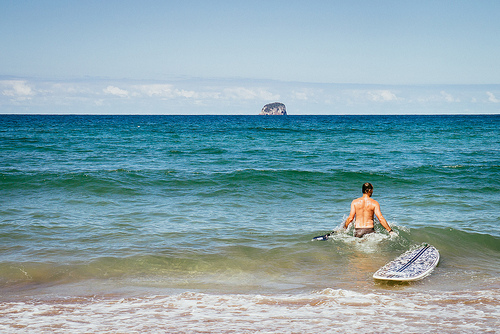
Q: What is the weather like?
A: It is clear.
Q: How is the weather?
A: It is clear.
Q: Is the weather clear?
A: Yes, it is clear.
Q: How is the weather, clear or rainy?
A: It is clear.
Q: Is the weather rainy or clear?
A: It is clear.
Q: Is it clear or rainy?
A: It is clear.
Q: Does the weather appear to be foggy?
A: No, it is clear.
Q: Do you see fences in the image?
A: No, there are no fences.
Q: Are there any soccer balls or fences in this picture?
A: No, there are no fences or soccer balls.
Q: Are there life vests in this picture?
A: No, there are no life vests.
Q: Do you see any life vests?
A: No, there are no life vests.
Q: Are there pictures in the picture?
A: No, there are no pictures.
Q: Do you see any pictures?
A: No, there are no pictures.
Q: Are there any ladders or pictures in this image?
A: No, there are no pictures or ladders.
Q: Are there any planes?
A: No, there are no planes.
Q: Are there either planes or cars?
A: No, there are no planes or cars.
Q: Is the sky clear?
A: Yes, the sky is clear.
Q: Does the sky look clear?
A: Yes, the sky is clear.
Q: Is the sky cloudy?
A: No, the sky is clear.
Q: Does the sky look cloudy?
A: No, the sky is clear.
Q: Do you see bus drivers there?
A: No, there are no bus drivers.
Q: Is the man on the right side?
A: Yes, the man is on the right of the image.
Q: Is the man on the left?
A: No, the man is on the right of the image.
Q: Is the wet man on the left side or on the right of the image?
A: The man is on the right of the image.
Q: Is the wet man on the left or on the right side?
A: The man is on the right of the image.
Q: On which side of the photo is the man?
A: The man is on the right of the image.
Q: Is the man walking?
A: Yes, the man is walking.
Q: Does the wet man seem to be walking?
A: Yes, the man is walking.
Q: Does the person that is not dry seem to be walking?
A: Yes, the man is walking.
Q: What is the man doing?
A: The man is walking.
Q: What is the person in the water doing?
A: The man is walking.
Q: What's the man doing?
A: The man is walking.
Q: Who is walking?
A: The man is walking.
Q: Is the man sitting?
A: No, the man is walking.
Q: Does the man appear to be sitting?
A: No, the man is walking.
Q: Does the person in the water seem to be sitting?
A: No, the man is walking.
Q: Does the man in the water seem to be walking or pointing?
A: The man is walking.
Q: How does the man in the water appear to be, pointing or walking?
A: The man is walking.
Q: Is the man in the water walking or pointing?
A: The man is walking.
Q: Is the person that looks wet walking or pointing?
A: The man is walking.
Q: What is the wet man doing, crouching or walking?
A: The man is walking.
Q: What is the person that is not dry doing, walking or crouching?
A: The man is walking.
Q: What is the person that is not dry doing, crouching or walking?
A: The man is walking.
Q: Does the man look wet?
A: Yes, the man is wet.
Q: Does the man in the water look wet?
A: Yes, the man is wet.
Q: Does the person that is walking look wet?
A: Yes, the man is wet.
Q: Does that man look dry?
A: No, the man is wet.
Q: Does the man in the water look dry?
A: No, the man is wet.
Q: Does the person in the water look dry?
A: No, the man is wet.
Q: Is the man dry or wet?
A: The man is wet.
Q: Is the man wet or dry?
A: The man is wet.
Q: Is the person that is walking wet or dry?
A: The man is wet.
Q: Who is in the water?
A: The man is in the water.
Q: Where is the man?
A: The man is in the water.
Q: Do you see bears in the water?
A: No, there is a man in the water.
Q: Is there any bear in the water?
A: No, there is a man in the water.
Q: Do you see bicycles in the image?
A: No, there are no bicycles.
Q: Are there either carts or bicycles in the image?
A: No, there are no bicycles or carts.